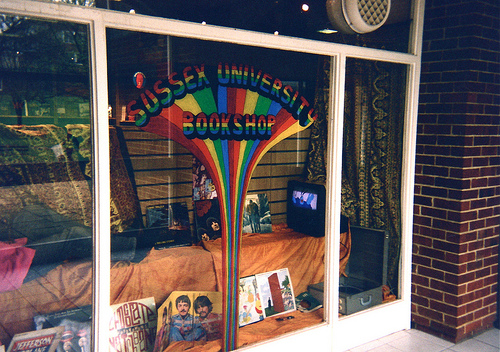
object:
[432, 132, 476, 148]
brick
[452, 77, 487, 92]
brick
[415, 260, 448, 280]
brick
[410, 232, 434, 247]
brick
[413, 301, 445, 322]
brick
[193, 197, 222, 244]
album cover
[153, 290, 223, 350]
album cover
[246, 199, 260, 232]
couple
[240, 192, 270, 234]
cover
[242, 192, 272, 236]
book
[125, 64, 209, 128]
sussex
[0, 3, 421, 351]
showcase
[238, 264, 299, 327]
book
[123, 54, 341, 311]
wrapping paper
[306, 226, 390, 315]
box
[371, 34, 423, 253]
frame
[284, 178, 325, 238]
tv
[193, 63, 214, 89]
x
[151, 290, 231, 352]
album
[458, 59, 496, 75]
bricks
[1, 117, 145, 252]
rug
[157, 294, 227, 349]
photo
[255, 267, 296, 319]
photo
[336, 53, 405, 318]
window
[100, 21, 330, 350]
window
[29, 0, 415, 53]
window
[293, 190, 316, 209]
screen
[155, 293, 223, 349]
four men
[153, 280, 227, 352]
book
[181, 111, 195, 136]
b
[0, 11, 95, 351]
window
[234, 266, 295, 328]
records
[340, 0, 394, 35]
air vent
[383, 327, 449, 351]
concrete tile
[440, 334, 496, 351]
concrete tile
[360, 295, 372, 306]
handle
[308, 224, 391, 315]
record player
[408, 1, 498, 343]
brick column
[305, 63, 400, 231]
curtains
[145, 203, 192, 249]
cover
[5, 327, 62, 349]
airplane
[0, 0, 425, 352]
bookstore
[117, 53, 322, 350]
design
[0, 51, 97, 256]
reflections